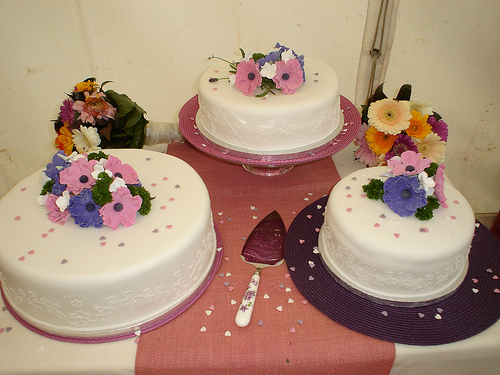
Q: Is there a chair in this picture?
A: No, there are no chairs.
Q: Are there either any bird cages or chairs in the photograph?
A: No, there are no chairs or bird cages.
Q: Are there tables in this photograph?
A: Yes, there is a table.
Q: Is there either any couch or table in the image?
A: Yes, there is a table.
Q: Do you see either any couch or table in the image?
A: Yes, there is a table.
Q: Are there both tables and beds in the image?
A: No, there is a table but no beds.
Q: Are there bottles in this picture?
A: No, there are no bottles.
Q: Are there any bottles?
A: No, there are no bottles.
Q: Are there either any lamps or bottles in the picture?
A: No, there are no bottles or lamps.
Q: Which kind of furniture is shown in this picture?
A: The furniture is a table.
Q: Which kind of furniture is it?
A: The piece of furniture is a table.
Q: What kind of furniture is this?
A: This is a table.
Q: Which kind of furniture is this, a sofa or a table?
A: This is a table.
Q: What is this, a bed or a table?
A: This is a table.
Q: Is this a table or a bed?
A: This is a table.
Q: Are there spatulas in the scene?
A: Yes, there is a spatula.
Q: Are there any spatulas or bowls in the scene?
A: Yes, there is a spatula.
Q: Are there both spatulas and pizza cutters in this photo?
A: No, there is a spatula but no pizza cutters.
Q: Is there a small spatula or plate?
A: Yes, there is a small spatula.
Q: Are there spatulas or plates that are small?
A: Yes, the spatula is small.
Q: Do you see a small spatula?
A: Yes, there is a small spatula.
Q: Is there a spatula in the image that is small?
A: Yes, there is a spatula that is small.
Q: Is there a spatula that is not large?
A: Yes, there is a small spatula.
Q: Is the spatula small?
A: Yes, the spatula is small.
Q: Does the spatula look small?
A: Yes, the spatula is small.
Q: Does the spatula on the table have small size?
A: Yes, the spatula is small.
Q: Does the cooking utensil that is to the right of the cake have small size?
A: Yes, the spatula is small.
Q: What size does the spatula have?
A: The spatula has small size.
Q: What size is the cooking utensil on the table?
A: The spatula is small.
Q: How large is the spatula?
A: The spatula is small.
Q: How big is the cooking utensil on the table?
A: The spatula is small.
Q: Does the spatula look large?
A: No, the spatula is small.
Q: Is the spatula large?
A: No, the spatula is small.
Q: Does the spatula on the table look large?
A: No, the spatula is small.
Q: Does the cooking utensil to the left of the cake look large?
A: No, the spatula is small.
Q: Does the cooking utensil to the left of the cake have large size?
A: No, the spatula is small.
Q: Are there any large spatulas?
A: No, there is a spatula but it is small.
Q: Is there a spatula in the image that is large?
A: No, there is a spatula but it is small.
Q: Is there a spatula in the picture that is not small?
A: No, there is a spatula but it is small.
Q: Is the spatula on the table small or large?
A: The spatula is small.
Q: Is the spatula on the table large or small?
A: The spatula is small.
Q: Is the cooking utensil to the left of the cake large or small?
A: The spatula is small.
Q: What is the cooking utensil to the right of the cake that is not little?
A: The cooking utensil is a spatula.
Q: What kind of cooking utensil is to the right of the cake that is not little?
A: The cooking utensil is a spatula.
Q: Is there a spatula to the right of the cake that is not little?
A: Yes, there is a spatula to the right of the cake.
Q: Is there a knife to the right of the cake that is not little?
A: No, there is a spatula to the right of the cake.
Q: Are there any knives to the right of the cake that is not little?
A: No, there is a spatula to the right of the cake.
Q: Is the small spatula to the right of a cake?
A: Yes, the spatula is to the right of a cake.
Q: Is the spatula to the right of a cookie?
A: No, the spatula is to the right of a cake.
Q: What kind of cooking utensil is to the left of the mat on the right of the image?
A: The cooking utensil is a spatula.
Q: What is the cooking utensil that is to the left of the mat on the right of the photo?
A: The cooking utensil is a spatula.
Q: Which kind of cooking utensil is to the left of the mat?
A: The cooking utensil is a spatula.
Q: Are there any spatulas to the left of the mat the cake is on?
A: Yes, there is a spatula to the left of the mat.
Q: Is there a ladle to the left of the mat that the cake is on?
A: No, there is a spatula to the left of the mat.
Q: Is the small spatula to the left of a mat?
A: Yes, the spatula is to the left of a mat.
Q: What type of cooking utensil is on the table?
A: The cooking utensil is a spatula.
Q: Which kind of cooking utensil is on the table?
A: The cooking utensil is a spatula.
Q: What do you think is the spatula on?
A: The spatula is on the table.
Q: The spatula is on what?
A: The spatula is on the table.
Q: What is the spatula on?
A: The spatula is on the table.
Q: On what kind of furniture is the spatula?
A: The spatula is on the table.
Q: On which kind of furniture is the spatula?
A: The spatula is on the table.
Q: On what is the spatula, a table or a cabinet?
A: The spatula is on a table.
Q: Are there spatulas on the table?
A: Yes, there is a spatula on the table.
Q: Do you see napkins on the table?
A: No, there is a spatula on the table.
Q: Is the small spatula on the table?
A: Yes, the spatula is on the table.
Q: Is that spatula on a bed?
A: No, the spatula is on the table.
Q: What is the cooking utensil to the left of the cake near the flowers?
A: The cooking utensil is a spatula.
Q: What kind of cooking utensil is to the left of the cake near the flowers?
A: The cooking utensil is a spatula.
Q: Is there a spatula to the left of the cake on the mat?
A: Yes, there is a spatula to the left of the cake.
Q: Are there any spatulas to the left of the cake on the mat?
A: Yes, there is a spatula to the left of the cake.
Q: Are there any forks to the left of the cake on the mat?
A: No, there is a spatula to the left of the cake.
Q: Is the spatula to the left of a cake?
A: Yes, the spatula is to the left of a cake.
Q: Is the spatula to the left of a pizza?
A: No, the spatula is to the left of a cake.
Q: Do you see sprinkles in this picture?
A: Yes, there are sprinkles.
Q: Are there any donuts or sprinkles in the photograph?
A: Yes, there are sprinkles.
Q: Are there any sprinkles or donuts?
A: Yes, there are sprinkles.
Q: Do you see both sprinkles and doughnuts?
A: No, there are sprinkles but no donuts.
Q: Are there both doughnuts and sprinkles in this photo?
A: No, there are sprinkles but no donuts.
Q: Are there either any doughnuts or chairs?
A: No, there are no chairs or doughnuts.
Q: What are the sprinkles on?
A: The sprinkles are on the cake.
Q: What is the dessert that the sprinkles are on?
A: The dessert is a cake.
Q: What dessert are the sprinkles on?
A: The sprinkles are on the cake.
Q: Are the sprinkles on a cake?
A: Yes, the sprinkles are on a cake.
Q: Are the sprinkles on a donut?
A: No, the sprinkles are on a cake.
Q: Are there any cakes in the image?
A: Yes, there is a cake.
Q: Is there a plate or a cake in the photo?
A: Yes, there is a cake.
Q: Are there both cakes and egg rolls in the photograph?
A: No, there is a cake but no egg rolls.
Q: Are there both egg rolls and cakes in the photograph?
A: No, there is a cake but no egg rolls.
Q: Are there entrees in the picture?
A: No, there are no entrees.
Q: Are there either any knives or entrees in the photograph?
A: No, there are no entrees or knives.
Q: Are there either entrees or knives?
A: No, there are no entrees or knives.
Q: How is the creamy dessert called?
A: The dessert is a cake.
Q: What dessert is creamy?
A: The dessert is a cake.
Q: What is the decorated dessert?
A: The dessert is a cake.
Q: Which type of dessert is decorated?
A: The dessert is a cake.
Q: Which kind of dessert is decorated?
A: The dessert is a cake.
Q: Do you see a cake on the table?
A: Yes, there is a cake on the table.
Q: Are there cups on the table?
A: No, there is a cake on the table.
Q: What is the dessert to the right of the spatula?
A: The dessert is a cake.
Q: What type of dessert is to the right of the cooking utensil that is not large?
A: The dessert is a cake.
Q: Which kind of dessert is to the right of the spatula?
A: The dessert is a cake.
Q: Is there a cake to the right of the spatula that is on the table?
A: Yes, there is a cake to the right of the spatula.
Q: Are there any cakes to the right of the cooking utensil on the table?
A: Yes, there is a cake to the right of the spatula.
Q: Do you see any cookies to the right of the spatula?
A: No, there is a cake to the right of the spatula.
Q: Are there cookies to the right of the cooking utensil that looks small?
A: No, there is a cake to the right of the spatula.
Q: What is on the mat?
A: The cake is on the mat.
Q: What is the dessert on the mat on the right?
A: The dessert is a cake.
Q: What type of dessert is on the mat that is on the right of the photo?
A: The dessert is a cake.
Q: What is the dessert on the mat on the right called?
A: The dessert is a cake.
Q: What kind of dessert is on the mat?
A: The dessert is a cake.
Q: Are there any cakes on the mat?
A: Yes, there is a cake on the mat.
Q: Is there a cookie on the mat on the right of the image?
A: No, there is a cake on the mat.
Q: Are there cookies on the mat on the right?
A: No, there is a cake on the mat.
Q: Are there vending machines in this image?
A: No, there are no vending machines.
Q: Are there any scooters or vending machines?
A: No, there are no vending machines or scooters.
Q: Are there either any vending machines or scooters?
A: No, there are no vending machines or scooters.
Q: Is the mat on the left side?
A: No, the mat is on the right of the image.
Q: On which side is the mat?
A: The mat is on the right of the image.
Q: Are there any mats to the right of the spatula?
A: Yes, there is a mat to the right of the spatula.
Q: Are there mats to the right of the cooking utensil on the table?
A: Yes, there is a mat to the right of the spatula.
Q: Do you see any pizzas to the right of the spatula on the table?
A: No, there is a mat to the right of the spatula.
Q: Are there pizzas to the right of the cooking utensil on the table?
A: No, there is a mat to the right of the spatula.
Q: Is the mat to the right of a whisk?
A: No, the mat is to the right of the spatula.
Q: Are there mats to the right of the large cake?
A: Yes, there is a mat to the right of the cake.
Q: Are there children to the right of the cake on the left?
A: No, there is a mat to the right of the cake.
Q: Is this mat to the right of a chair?
A: No, the mat is to the right of the cake.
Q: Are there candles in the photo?
A: No, there are no candles.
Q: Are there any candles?
A: No, there are no candles.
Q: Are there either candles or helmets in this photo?
A: No, there are no candles or helmets.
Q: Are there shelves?
A: No, there are no shelves.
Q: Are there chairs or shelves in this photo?
A: No, there are no shelves or chairs.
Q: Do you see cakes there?
A: Yes, there is a cake.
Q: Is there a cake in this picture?
A: Yes, there is a cake.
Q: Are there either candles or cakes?
A: Yes, there is a cake.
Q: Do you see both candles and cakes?
A: No, there is a cake but no candles.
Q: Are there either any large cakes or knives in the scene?
A: Yes, there is a large cake.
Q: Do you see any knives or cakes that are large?
A: Yes, the cake is large.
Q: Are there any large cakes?
A: Yes, there is a large cake.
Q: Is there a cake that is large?
A: Yes, there is a cake that is large.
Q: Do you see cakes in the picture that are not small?
A: Yes, there is a large cake.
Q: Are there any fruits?
A: No, there are no fruits.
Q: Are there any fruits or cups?
A: No, there are no fruits or cups.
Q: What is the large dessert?
A: The dessert is a cake.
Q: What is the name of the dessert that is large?
A: The dessert is a cake.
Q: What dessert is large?
A: The dessert is a cake.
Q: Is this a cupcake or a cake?
A: This is a cake.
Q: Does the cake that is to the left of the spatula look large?
A: Yes, the cake is large.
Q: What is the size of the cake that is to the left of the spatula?
A: The cake is large.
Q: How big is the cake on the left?
A: The cake is large.